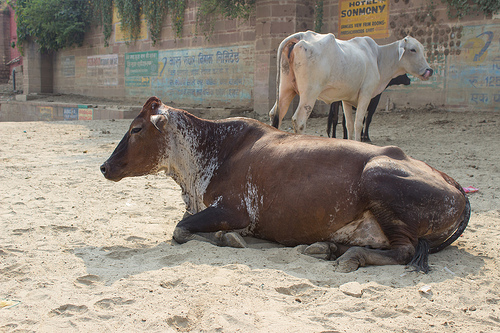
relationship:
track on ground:
[77, 272, 101, 291] [2, 119, 499, 327]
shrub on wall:
[5, 1, 90, 48] [54, 1, 498, 112]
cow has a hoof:
[101, 95, 472, 274] [216, 230, 250, 252]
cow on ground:
[101, 95, 472, 274] [2, 119, 499, 327]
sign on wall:
[337, 0, 390, 40] [54, 1, 498, 112]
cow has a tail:
[101, 95, 472, 274] [404, 198, 473, 273]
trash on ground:
[463, 184, 482, 195] [2, 119, 499, 327]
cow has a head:
[101, 95, 472, 274] [99, 96, 179, 184]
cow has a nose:
[101, 95, 472, 274] [97, 157, 124, 183]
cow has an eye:
[101, 95, 472, 274] [129, 124, 143, 135]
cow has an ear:
[101, 95, 472, 274] [150, 113, 166, 131]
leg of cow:
[172, 203, 247, 251] [101, 95, 472, 274]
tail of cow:
[404, 198, 473, 273] [101, 95, 472, 274]